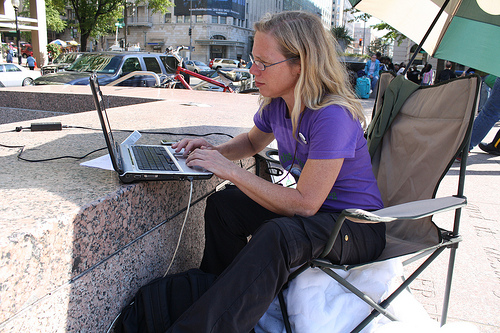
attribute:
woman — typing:
[250, 21, 374, 267]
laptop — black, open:
[88, 73, 185, 194]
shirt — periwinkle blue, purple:
[278, 104, 382, 217]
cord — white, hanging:
[184, 178, 198, 233]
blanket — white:
[301, 274, 417, 330]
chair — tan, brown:
[379, 76, 479, 242]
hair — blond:
[293, 33, 346, 103]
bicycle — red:
[171, 49, 240, 95]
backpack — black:
[128, 266, 205, 331]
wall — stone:
[115, 191, 173, 249]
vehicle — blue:
[70, 55, 174, 72]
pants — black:
[215, 208, 339, 263]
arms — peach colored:
[274, 120, 351, 200]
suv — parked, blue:
[63, 57, 191, 82]